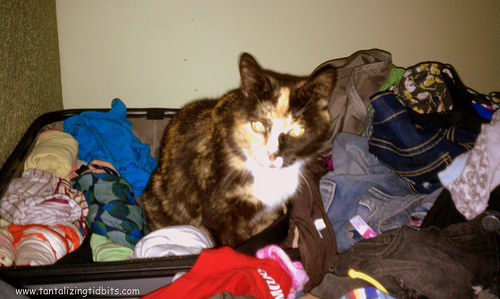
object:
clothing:
[75, 164, 146, 259]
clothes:
[322, 46, 498, 249]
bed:
[0, 94, 497, 297]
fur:
[166, 126, 203, 170]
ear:
[302, 63, 341, 95]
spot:
[243, 154, 307, 212]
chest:
[0, 102, 315, 278]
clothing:
[0, 101, 159, 267]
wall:
[0, 0, 57, 161]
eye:
[288, 124, 307, 138]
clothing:
[62, 99, 155, 196]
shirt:
[144, 245, 293, 297]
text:
[257, 266, 285, 298]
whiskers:
[204, 135, 253, 187]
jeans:
[319, 132, 418, 253]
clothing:
[88, 231, 134, 266]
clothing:
[360, 94, 469, 185]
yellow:
[43, 144, 75, 174]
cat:
[152, 51, 345, 255]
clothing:
[27, 125, 80, 176]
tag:
[348, 214, 378, 242]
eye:
[236, 121, 269, 133]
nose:
[264, 141, 284, 164]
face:
[236, 84, 328, 170]